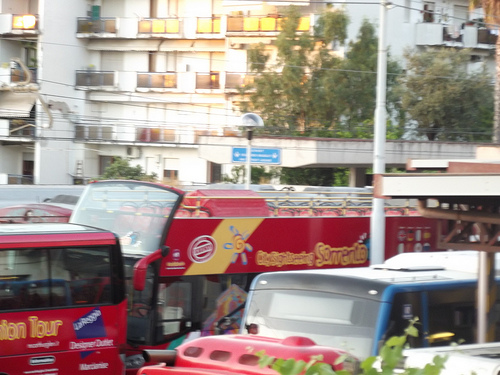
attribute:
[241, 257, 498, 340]
bus — blue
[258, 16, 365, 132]
green tree — large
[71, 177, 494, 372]
bus — TALL, YELLOW, RED, passenger bus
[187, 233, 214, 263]
logo — round, red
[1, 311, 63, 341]
words — yellow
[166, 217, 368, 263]
paint — red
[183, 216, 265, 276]
stripe — yellow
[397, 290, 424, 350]
window — in front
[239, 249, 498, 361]
bus — front has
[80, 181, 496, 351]
bus — red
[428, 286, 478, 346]
window — with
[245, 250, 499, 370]
bus — blue, has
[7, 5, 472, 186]
building — white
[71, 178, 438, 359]
bus — blue and white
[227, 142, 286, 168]
street sign — blue, white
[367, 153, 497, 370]
area — covered